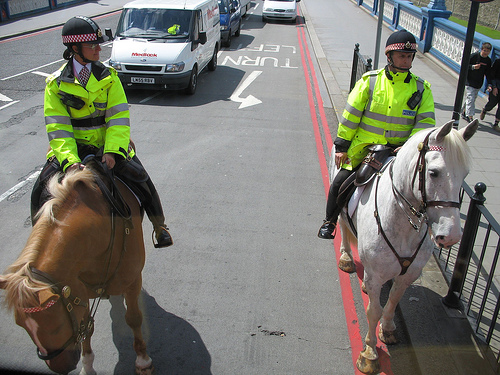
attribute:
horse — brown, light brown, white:
[4, 162, 150, 369]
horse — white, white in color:
[332, 122, 478, 371]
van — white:
[105, 1, 223, 95]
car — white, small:
[262, 0, 299, 24]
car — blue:
[218, 3, 243, 46]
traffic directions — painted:
[215, 39, 298, 111]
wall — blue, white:
[357, 2, 500, 83]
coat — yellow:
[42, 59, 132, 158]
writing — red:
[129, 51, 158, 60]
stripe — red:
[290, 4, 387, 371]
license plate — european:
[131, 77, 156, 86]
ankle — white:
[134, 349, 149, 369]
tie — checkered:
[78, 64, 88, 84]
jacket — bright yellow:
[336, 67, 434, 162]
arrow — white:
[229, 69, 263, 111]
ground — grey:
[1, 6, 425, 373]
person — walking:
[464, 42, 488, 121]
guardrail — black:
[437, 171, 499, 348]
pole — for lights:
[454, 3, 474, 133]